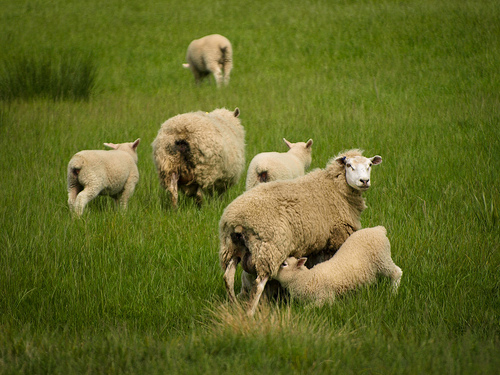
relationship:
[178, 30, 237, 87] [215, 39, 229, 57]
sheep has tail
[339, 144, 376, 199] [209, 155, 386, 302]
head turned around on sheep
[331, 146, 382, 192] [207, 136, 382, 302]
head on sheep